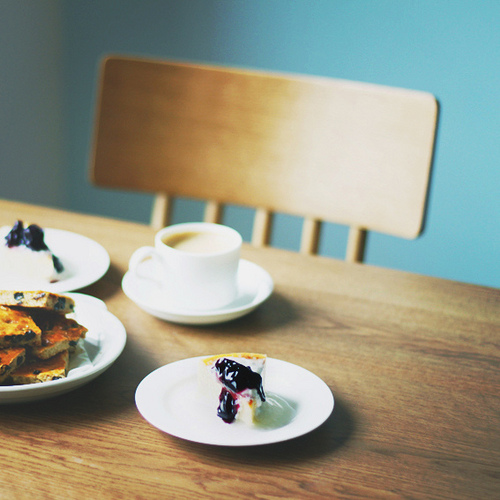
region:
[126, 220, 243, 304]
A small cup of coffee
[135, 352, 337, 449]
White porcelain dessert saucer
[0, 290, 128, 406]
White porcelain plate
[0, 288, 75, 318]
Delicious chocolate chip cookie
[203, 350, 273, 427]
Delicious blueberry cheesecake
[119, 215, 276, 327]
Saucer with a cup on it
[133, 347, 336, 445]
Saucer with dessert on it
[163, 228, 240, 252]
Coffee with creamer in it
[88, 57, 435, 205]
Back of a wooden chair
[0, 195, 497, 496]
large wooden table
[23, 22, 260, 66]
The wall is blue.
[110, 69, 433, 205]
A chair is next to the table.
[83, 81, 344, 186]
The chair is made of wood.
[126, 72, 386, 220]
The chair is tan in color.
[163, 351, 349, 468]
The dish is circular.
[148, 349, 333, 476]
The dish is white.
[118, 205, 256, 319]
The mug is white.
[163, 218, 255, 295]
A drink is in the mug.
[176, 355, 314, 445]
There is food on the plate.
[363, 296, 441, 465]
The table is made of wood.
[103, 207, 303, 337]
White cup and saucer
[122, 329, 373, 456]
White plate with dessert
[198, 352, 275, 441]
Jam topping on slice of dessert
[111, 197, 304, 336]
Cup of coffee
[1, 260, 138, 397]
White plate piled with baked goods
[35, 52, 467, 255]
Wooden chair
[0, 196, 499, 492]
Wooden table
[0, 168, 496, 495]
Baked goods and desserts sitting on table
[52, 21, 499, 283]
Blue wall in room with table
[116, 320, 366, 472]
Cheesecake with blueberry toppings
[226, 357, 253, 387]
blackberry sauce on a cream pie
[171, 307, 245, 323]
the edge of a white saucer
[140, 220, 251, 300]
a cup of coffee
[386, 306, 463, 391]
a smooth brown table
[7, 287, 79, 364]
a plate of chocolate squares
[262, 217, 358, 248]
wooden slats in a chair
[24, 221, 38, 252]
blackberries on top of a pie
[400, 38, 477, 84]
a blue wall behind the chair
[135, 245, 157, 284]
a handle on a mug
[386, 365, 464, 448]
wood grains in the table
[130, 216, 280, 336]
There is coffee in the cup.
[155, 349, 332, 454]
There is pie on the plate.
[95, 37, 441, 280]
There is a chair by the table.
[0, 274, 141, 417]
There is food on the plate.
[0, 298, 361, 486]
Two plates with food.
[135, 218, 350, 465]
Coffee cup next plate with a slice of pie.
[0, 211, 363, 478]
There are three plates and a cup on the table.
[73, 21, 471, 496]
The chair and the table are made out of wood.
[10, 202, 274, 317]
There is a plate of food on the left-side of the coffee cup.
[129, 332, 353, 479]
The plate of food is on a wood table.